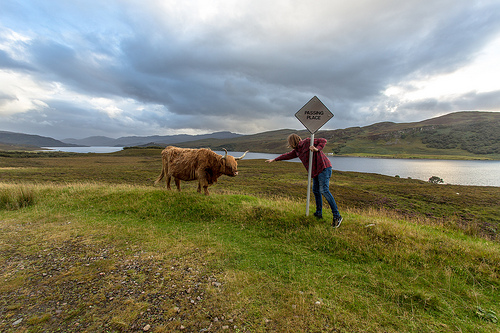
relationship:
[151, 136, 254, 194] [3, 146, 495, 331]
bull on grass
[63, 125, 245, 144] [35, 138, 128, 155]
hill across water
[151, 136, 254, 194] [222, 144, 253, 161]
bull has horns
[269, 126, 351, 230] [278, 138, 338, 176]
woman wears sweater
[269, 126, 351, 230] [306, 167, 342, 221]
woman wears blue jeans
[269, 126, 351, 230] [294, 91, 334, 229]
woman holding sign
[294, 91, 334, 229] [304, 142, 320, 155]
sign in left hand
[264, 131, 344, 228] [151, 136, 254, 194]
woman reaching for cow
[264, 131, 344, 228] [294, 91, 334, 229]
woman standing by sign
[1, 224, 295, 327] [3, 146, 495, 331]
pebbles on grass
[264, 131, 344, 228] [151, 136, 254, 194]
woman feeding bull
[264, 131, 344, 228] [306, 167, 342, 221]
woman wearing blue jeans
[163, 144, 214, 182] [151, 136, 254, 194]
fur on cow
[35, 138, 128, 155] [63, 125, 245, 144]
water by hill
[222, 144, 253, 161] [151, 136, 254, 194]
horns on bull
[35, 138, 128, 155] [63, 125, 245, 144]
water between hill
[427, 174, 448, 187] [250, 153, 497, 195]
tree on waterside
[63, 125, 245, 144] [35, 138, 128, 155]
hill beside water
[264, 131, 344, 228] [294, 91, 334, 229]
woman holding sign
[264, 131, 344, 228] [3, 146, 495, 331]
woman in field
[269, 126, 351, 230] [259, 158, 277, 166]
woman holding hand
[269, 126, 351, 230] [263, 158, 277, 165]
woman reaching out hand